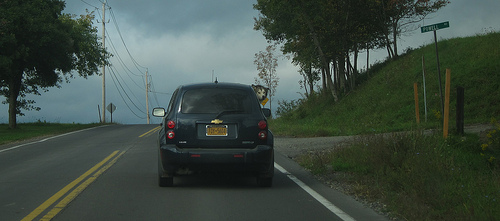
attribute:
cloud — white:
[164, 35, 234, 65]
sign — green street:
[417, 16, 454, 37]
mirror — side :
[147, 103, 172, 117]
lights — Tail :
[163, 114, 276, 147]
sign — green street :
[408, 21, 458, 38]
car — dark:
[152, 78, 275, 185]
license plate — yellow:
[201, 121, 232, 138]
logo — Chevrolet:
[208, 114, 226, 129]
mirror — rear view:
[151, 105, 167, 124]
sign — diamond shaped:
[103, 101, 119, 116]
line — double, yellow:
[19, 146, 127, 219]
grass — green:
[298, 125, 498, 215]